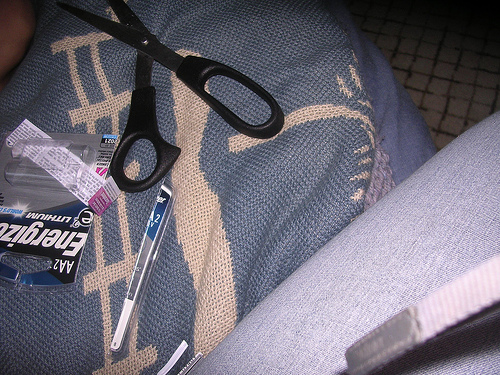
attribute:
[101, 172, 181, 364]
strip — plastic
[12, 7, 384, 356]
blanket — blue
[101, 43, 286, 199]
handle — scissor, large black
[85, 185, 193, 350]
case — opened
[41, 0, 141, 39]
blades —  scissors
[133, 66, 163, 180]
strap — leather strip 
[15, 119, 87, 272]
plastic — packageing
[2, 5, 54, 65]
skin — person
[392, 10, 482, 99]
floor — light brown